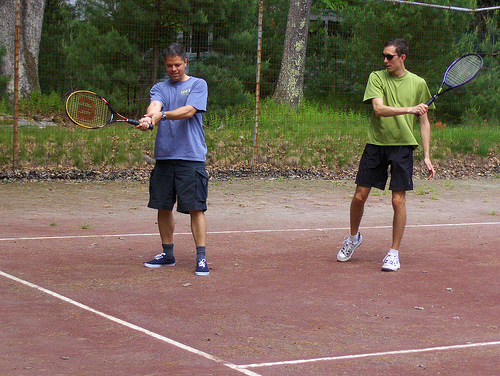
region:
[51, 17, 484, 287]
two tennis players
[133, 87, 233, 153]
tennis player holding his wrist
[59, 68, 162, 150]
man holding a yellow tennis racket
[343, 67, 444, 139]
man with a green T-shirt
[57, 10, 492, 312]
two man standing on a tennis court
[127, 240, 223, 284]
man wearing blue tennis shoes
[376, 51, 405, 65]
black sunglasses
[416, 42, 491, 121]
a purple tennis racket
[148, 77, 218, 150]
man wearing a blue shirt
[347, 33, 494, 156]
man swinging a tennis racket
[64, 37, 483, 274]
two male tennis players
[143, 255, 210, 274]
man's pair of blue shoes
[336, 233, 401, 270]
man's pair of white shoes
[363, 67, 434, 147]
man's short sleeved green shirt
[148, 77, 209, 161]
man's short sleeved blue shirt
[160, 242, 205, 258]
the man's blue socks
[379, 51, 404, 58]
the man's sun glasses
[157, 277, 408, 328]
ground of the tennis court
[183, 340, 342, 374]
white lines on the court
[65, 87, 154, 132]
tennis racquet with yellow on the rim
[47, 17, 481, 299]
Two men holding tennis rackets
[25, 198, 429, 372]
Red court with white lines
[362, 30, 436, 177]
Man is wearing green shirt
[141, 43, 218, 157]
Man is wearing a blue shirt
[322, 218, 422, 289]
Man has white shoes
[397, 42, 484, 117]
Blue and black tennis racket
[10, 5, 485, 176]
Thin black mesh net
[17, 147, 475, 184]
Pile of brown leaves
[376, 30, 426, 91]
Man has black sunglasses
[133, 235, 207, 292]
Man has blue and white shoes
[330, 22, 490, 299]
A man in green swinging a tennis racket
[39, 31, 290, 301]
A man in blue holding a tennis racket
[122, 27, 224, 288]
A man in a blue shirt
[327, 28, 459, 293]
A man in a green shirt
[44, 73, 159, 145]
A yellow and red tennis racket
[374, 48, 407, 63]
A pair of sunglasses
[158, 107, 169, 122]
A watch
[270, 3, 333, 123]
A tree with moss on it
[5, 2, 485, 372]
A fenced in tennis court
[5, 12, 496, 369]
Two men in a tennis court practicing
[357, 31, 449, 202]
the shirt is green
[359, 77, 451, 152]
the shirt is green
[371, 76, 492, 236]
the shirt is green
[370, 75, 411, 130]
the shirt is green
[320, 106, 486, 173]
the shirt is green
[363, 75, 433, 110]
the shirt is green